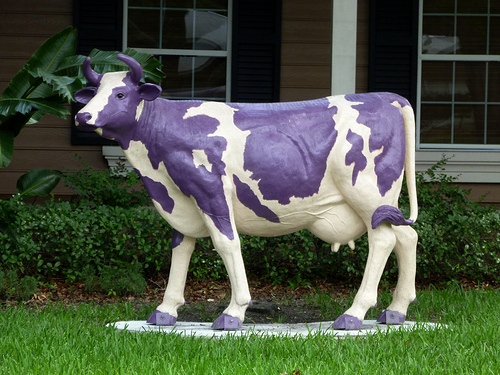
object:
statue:
[69, 53, 419, 332]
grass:
[6, 295, 495, 367]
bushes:
[0, 58, 165, 199]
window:
[119, 3, 497, 88]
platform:
[106, 312, 446, 339]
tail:
[371, 97, 420, 230]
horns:
[81, 53, 144, 81]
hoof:
[210, 313, 243, 331]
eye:
[115, 93, 128, 101]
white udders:
[307, 204, 367, 253]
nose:
[73, 112, 92, 123]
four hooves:
[138, 309, 406, 330]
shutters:
[74, 7, 232, 52]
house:
[10, 6, 496, 94]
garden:
[4, 5, 500, 375]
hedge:
[3, 193, 169, 275]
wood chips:
[35, 282, 155, 305]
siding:
[80, 4, 179, 54]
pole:
[331, 0, 357, 96]